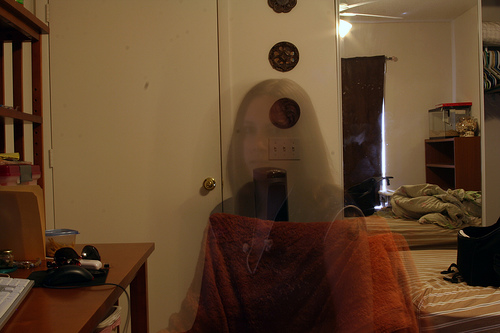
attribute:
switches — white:
[265, 139, 304, 162]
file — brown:
[3, 184, 50, 270]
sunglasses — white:
[54, 237, 100, 265]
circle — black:
[268, 97, 301, 127]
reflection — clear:
[173, 77, 376, 332]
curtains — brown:
[337, 55, 412, 220]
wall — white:
[36, 41, 493, 260]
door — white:
[49, 3, 221, 326]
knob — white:
[189, 170, 254, 210]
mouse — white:
[26, 263, 97, 293]